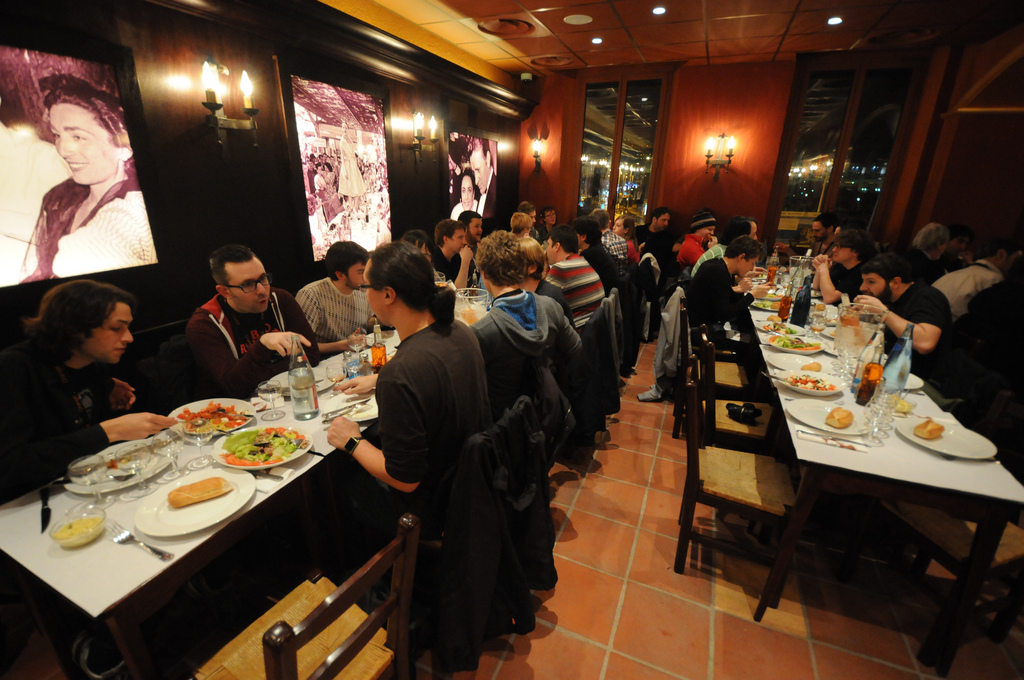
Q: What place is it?
A: It is a restaurant.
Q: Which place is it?
A: It is a restaurant.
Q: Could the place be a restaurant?
A: Yes, it is a restaurant.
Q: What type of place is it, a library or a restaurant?
A: It is a restaurant.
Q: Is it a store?
A: No, it is a restaurant.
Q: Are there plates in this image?
A: Yes, there is a plate.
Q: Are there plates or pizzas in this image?
A: Yes, there is a plate.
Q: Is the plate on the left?
A: Yes, the plate is on the left of the image.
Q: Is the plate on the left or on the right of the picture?
A: The plate is on the left of the image.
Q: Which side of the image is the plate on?
A: The plate is on the left of the image.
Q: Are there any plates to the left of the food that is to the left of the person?
A: Yes, there is a plate to the left of the food.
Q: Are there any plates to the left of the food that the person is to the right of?
A: Yes, there is a plate to the left of the food.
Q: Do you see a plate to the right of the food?
A: No, the plate is to the left of the food.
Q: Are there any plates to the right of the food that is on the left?
A: No, the plate is to the left of the food.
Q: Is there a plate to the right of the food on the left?
A: No, the plate is to the left of the food.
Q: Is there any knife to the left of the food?
A: No, there is a plate to the left of the food.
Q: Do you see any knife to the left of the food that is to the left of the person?
A: No, there is a plate to the left of the food.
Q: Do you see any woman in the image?
A: Yes, there is a woman.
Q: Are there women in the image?
A: Yes, there is a woman.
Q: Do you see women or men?
A: Yes, there is a woman.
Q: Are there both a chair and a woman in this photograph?
A: Yes, there are both a woman and a chair.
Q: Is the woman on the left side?
A: Yes, the woman is on the left of the image.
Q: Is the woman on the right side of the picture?
A: No, the woman is on the left of the image.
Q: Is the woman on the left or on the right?
A: The woman is on the left of the image.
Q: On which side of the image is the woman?
A: The woman is on the left of the image.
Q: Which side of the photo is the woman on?
A: The woman is on the left of the image.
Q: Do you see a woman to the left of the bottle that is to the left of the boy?
A: Yes, there is a woman to the left of the bottle.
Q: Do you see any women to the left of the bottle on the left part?
A: Yes, there is a woman to the left of the bottle.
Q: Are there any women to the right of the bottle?
A: No, the woman is to the left of the bottle.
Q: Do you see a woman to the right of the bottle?
A: No, the woman is to the left of the bottle.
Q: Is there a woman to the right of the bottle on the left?
A: No, the woman is to the left of the bottle.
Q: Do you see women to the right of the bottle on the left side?
A: No, the woman is to the left of the bottle.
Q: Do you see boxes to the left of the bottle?
A: No, there is a woman to the left of the bottle.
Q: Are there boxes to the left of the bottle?
A: No, there is a woman to the left of the bottle.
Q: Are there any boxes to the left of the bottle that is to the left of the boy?
A: No, there is a woman to the left of the bottle.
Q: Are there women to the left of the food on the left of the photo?
A: Yes, there is a woman to the left of the food.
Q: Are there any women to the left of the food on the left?
A: Yes, there is a woman to the left of the food.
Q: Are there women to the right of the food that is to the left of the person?
A: No, the woman is to the left of the food.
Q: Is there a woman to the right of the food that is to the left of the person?
A: No, the woman is to the left of the food.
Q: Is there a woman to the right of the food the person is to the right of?
A: No, the woman is to the left of the food.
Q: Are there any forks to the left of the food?
A: No, there is a woman to the left of the food.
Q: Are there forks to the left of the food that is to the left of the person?
A: No, there is a woman to the left of the food.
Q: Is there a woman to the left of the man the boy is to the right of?
A: Yes, there is a woman to the left of the man.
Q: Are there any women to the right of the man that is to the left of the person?
A: No, the woman is to the left of the man.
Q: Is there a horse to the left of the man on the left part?
A: No, there is a woman to the left of the man.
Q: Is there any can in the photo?
A: No, there are no cans.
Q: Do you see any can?
A: No, there are no cans.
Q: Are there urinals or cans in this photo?
A: No, there are no cans or urinals.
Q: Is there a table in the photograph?
A: Yes, there is a table.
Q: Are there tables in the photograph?
A: Yes, there is a table.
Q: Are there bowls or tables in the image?
A: Yes, there is a table.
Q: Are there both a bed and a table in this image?
A: No, there is a table but no beds.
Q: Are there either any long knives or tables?
A: Yes, there is a long table.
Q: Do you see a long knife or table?
A: Yes, there is a long table.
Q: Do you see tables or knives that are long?
A: Yes, the table is long.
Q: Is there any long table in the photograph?
A: Yes, there is a long table.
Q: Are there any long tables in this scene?
A: Yes, there is a long table.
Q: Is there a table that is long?
A: Yes, there is a table that is long.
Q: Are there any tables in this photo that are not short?
A: Yes, there is a long table.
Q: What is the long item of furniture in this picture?
A: The piece of furniture is a table.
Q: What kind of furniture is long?
A: The furniture is a table.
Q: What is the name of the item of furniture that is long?
A: The piece of furniture is a table.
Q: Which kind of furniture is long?
A: The furniture is a table.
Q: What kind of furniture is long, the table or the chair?
A: The table is long.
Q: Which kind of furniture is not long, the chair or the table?
A: The chair is not long.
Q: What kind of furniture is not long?
A: The furniture is a chair.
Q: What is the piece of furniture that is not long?
A: The piece of furniture is a chair.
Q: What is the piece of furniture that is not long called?
A: The piece of furniture is a chair.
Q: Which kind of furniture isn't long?
A: The furniture is a chair.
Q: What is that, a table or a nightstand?
A: That is a table.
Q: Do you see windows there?
A: Yes, there is a window.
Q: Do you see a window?
A: Yes, there is a window.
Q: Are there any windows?
A: Yes, there is a window.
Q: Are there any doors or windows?
A: Yes, there is a window.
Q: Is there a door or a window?
A: Yes, there is a window.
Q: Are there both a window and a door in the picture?
A: No, there is a window but no doors.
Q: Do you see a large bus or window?
A: Yes, there is a large window.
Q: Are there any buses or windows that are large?
A: Yes, the window is large.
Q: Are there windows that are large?
A: Yes, there is a window that is large.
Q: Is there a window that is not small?
A: Yes, there is a large window.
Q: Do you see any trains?
A: No, there are no trains.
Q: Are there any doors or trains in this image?
A: No, there are no trains or doors.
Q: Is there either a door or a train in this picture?
A: No, there are no trains or doors.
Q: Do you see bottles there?
A: Yes, there is a bottle.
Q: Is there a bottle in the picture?
A: Yes, there is a bottle.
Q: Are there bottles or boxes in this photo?
A: Yes, there is a bottle.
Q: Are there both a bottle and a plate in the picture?
A: Yes, there are both a bottle and a plate.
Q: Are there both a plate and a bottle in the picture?
A: Yes, there are both a bottle and a plate.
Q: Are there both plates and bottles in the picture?
A: Yes, there are both a bottle and a plate.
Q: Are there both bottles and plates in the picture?
A: Yes, there are both a bottle and a plate.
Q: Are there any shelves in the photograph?
A: No, there are no shelves.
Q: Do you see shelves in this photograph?
A: No, there are no shelves.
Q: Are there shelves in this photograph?
A: No, there are no shelves.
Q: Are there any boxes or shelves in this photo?
A: No, there are no shelves or boxes.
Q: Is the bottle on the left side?
A: Yes, the bottle is on the left of the image.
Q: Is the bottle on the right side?
A: No, the bottle is on the left of the image.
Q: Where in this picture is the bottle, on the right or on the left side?
A: The bottle is on the left of the image.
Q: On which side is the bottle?
A: The bottle is on the left of the image.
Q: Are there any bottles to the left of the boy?
A: Yes, there is a bottle to the left of the boy.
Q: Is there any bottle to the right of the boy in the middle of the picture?
A: No, the bottle is to the left of the boy.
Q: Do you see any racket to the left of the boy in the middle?
A: No, there is a bottle to the left of the boy.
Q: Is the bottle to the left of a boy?
A: Yes, the bottle is to the left of a boy.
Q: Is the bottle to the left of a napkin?
A: No, the bottle is to the left of a boy.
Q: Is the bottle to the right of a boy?
A: No, the bottle is to the left of a boy.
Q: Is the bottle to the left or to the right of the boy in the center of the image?
A: The bottle is to the left of the boy.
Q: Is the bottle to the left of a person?
A: Yes, the bottle is to the left of a person.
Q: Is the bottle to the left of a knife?
A: No, the bottle is to the left of a person.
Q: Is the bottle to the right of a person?
A: No, the bottle is to the left of a person.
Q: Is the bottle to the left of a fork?
A: No, the bottle is to the left of a person.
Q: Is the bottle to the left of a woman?
A: No, the bottle is to the right of a woman.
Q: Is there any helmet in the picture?
A: No, there are no helmets.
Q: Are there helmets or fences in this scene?
A: No, there are no helmets or fences.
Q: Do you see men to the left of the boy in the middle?
A: Yes, there is a man to the left of the boy.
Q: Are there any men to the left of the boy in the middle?
A: Yes, there is a man to the left of the boy.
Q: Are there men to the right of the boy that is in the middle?
A: No, the man is to the left of the boy.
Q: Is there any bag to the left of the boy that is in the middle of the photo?
A: No, there is a man to the left of the boy.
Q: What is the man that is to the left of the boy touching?
A: The man is touching the glass.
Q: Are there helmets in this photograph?
A: No, there are no helmets.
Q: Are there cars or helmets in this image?
A: No, there are no helmets or cars.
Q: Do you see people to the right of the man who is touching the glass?
A: Yes, there is a person to the right of the man.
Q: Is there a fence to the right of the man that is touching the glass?
A: No, there is a person to the right of the man.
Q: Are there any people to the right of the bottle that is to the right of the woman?
A: Yes, there is a person to the right of the bottle.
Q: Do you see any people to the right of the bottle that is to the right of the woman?
A: Yes, there is a person to the right of the bottle.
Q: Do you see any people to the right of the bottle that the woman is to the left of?
A: Yes, there is a person to the right of the bottle.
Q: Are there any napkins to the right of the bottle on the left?
A: No, there is a person to the right of the bottle.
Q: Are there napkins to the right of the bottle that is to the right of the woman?
A: No, there is a person to the right of the bottle.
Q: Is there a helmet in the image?
A: No, there are no helmets.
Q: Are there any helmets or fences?
A: No, there are no helmets or fences.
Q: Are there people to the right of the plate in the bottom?
A: Yes, there is a person to the right of the plate.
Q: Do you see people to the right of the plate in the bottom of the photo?
A: Yes, there is a person to the right of the plate.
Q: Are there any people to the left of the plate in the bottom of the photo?
A: No, the person is to the right of the plate.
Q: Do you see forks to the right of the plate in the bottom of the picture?
A: No, there is a person to the right of the plate.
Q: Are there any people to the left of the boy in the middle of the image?
A: Yes, there is a person to the left of the boy.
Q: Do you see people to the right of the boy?
A: No, the person is to the left of the boy.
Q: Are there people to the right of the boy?
A: No, the person is to the left of the boy.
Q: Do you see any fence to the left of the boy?
A: No, there is a person to the left of the boy.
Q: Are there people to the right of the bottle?
A: Yes, there is a person to the right of the bottle.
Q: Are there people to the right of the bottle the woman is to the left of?
A: Yes, there is a person to the right of the bottle.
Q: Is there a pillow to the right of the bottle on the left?
A: No, there is a person to the right of the bottle.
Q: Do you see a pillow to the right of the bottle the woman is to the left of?
A: No, there is a person to the right of the bottle.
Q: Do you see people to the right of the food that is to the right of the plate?
A: Yes, there is a person to the right of the food.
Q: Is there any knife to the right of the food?
A: No, there is a person to the right of the food.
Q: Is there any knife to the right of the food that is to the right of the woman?
A: No, there is a person to the right of the food.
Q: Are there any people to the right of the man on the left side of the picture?
A: Yes, there is a person to the right of the man.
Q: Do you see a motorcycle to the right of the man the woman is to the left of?
A: No, there is a person to the right of the man.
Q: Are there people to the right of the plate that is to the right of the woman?
A: Yes, there is a person to the right of the plate.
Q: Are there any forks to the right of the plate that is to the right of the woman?
A: No, there is a person to the right of the plate.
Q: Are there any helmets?
A: No, there are no helmets.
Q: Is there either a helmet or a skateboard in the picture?
A: No, there are no helmets or skateboards.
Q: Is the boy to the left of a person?
A: No, the boy is to the right of a person.